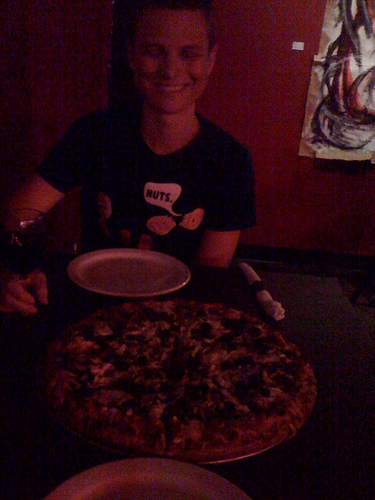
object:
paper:
[299, 0, 375, 160]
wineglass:
[0, 208, 42, 292]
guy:
[0, 0, 250, 315]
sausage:
[192, 323, 213, 340]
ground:
[241, 133, 262, 145]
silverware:
[251, 280, 265, 301]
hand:
[0, 269, 48, 315]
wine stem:
[18, 275, 26, 285]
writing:
[146, 189, 170, 202]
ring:
[251, 281, 268, 297]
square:
[293, 42, 304, 50]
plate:
[67, 247, 190, 296]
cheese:
[48, 300, 315, 455]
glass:
[0, 208, 41, 274]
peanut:
[147, 209, 205, 235]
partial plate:
[45, 456, 245, 500]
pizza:
[40, 302, 316, 457]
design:
[144, 182, 181, 217]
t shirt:
[32, 105, 257, 265]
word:
[146, 189, 170, 202]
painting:
[299, 3, 374, 161]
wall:
[0, 0, 373, 255]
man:
[0, 0, 240, 313]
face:
[134, 11, 207, 112]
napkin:
[241, 264, 285, 321]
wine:
[5, 242, 36, 270]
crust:
[199, 384, 297, 456]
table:
[0, 266, 375, 500]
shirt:
[36, 105, 255, 265]